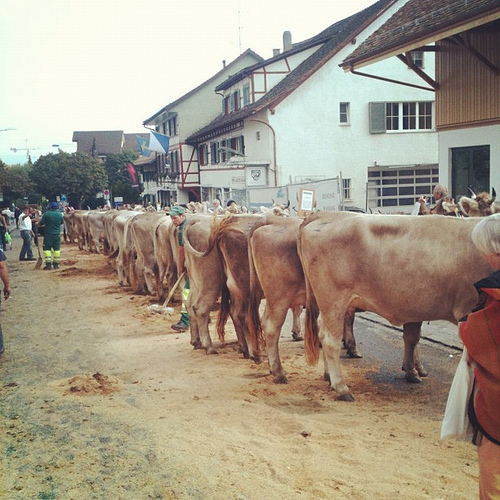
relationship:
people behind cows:
[1, 183, 450, 354] [65, 189, 499, 402]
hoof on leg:
[335, 392, 356, 403] [301, 231, 355, 402]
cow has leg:
[297, 211, 495, 404] [301, 231, 355, 402]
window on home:
[339, 103, 347, 124] [186, 3, 437, 211]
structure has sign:
[247, 170, 344, 218] [298, 190, 314, 211]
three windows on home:
[384, 99, 433, 131] [186, 3, 437, 211]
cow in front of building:
[297, 211, 495, 404] [337, 1, 499, 208]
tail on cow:
[297, 217, 322, 365] [297, 211, 495, 404]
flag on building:
[148, 130, 169, 155] [143, 48, 268, 212]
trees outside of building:
[1, 138, 139, 211] [143, 48, 268, 212]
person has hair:
[420, 184, 449, 216] [435, 186, 449, 200]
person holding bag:
[420, 184, 449, 216] [412, 203, 422, 215]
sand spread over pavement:
[1, 236, 480, 498] [1, 229, 482, 498]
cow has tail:
[180, 214, 235, 354] [183, 210, 239, 259]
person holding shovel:
[37, 202, 65, 271] [34, 226, 44, 271]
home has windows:
[186, 3, 437, 211] [201, 49, 439, 208]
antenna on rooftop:
[236, 3, 245, 56] [143, 46, 266, 128]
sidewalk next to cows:
[357, 311, 464, 351] [65, 189, 499, 402]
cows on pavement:
[65, 189, 499, 402] [1, 229, 482, 498]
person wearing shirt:
[37, 202, 65, 271] [40, 209, 65, 233]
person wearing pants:
[37, 202, 65, 271] [43, 235, 61, 264]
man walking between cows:
[167, 207, 192, 332] [65, 189, 499, 402]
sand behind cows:
[1, 236, 480, 498] [65, 189, 499, 402]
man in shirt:
[18, 206, 35, 261] [18, 213, 32, 231]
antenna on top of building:
[236, 3, 245, 56] [143, 48, 268, 212]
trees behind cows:
[1, 138, 139, 211] [65, 189, 499, 402]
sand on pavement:
[1, 236, 480, 498] [1, 229, 482, 498]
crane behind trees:
[9, 138, 60, 161] [1, 138, 139, 211]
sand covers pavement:
[1, 236, 480, 498] [1, 229, 482, 498]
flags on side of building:
[126, 133, 169, 184] [143, 48, 268, 212]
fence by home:
[217, 188, 248, 217] [186, 3, 437, 211]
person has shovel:
[37, 202, 65, 271] [34, 226, 44, 271]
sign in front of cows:
[298, 190, 314, 211] [65, 189, 499, 402]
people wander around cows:
[1, 183, 450, 354] [65, 189, 499, 402]